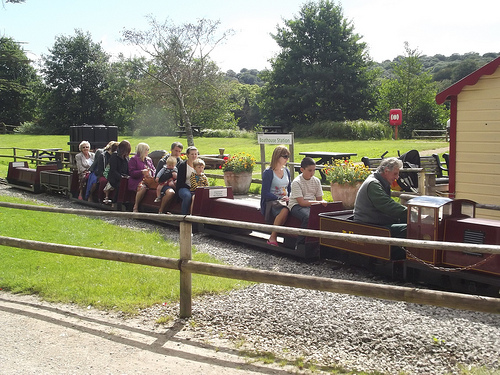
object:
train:
[7, 160, 499, 297]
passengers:
[287, 157, 322, 249]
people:
[76, 141, 94, 199]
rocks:
[224, 290, 234, 298]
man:
[353, 156, 408, 237]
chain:
[400, 247, 498, 272]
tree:
[257, 0, 379, 123]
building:
[435, 56, 500, 220]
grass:
[3, 258, 118, 282]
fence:
[0, 201, 499, 316]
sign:
[258, 134, 292, 146]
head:
[376, 158, 401, 183]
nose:
[395, 174, 400, 181]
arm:
[367, 181, 407, 216]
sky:
[2, 2, 187, 25]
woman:
[261, 147, 292, 247]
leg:
[268, 199, 289, 238]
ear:
[384, 168, 390, 176]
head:
[269, 147, 289, 169]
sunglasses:
[278, 154, 288, 160]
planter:
[222, 170, 249, 195]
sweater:
[260, 166, 290, 214]